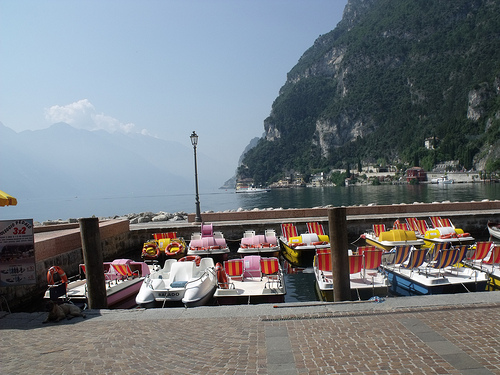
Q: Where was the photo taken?
A: Boat docks.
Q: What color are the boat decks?
A: White.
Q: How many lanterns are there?
A: 1.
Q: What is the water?
A: Boats.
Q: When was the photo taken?
A: Daytime.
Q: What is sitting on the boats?
A: Chairs.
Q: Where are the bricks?
A: On sidewalk.